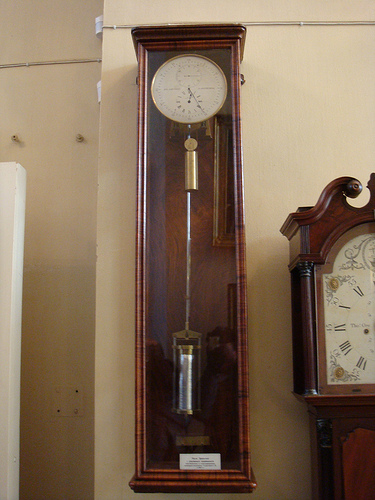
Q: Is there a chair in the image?
A: No, there are no chairs.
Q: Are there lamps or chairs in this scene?
A: No, there are no chairs or lamps.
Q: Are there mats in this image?
A: No, there are no mats.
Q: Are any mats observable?
A: No, there are no mats.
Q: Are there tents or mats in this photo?
A: No, there are no mats or tents.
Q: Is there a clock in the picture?
A: Yes, there is a clock.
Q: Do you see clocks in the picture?
A: Yes, there is a clock.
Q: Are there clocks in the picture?
A: Yes, there is a clock.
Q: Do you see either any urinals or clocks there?
A: Yes, there is a clock.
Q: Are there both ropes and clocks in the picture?
A: No, there is a clock but no ropes.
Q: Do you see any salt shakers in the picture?
A: No, there are no salt shakers.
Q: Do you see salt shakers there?
A: No, there are no salt shakers.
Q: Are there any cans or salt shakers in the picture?
A: No, there are no salt shakers or cans.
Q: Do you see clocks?
A: Yes, there is a clock.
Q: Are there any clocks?
A: Yes, there is a clock.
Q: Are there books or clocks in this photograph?
A: Yes, there is a clock.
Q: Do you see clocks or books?
A: Yes, there is a clock.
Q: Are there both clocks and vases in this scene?
A: No, there is a clock but no vases.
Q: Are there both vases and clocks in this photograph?
A: No, there is a clock but no vases.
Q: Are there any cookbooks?
A: No, there are no cookbooks.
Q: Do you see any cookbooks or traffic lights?
A: No, there are no cookbooks or traffic lights.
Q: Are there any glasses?
A: No, there are no glasses.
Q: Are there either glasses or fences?
A: No, there are no glasses or fences.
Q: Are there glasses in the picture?
A: No, there are no glasses.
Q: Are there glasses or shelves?
A: No, there are no glasses or shelves.